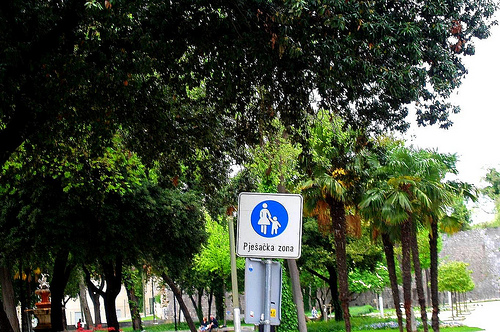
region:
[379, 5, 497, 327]
bright skies over trees and building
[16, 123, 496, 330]
grove of different types of green trees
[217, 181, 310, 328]
poles on either side of signs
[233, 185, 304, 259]
square sign with mother holding hands with child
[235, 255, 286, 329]
stickers placed on the back of a sign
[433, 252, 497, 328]
row of bright green trees at end of open lot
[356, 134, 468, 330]
narrow and long leaves on rough trunks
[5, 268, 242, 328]
tiered water fountain and buildings through trees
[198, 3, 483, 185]
dark green leaves over green and yellowish green leaves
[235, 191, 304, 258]
black print on sign in non-English language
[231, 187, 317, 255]
a white and blue sign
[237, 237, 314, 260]
black letters on a sign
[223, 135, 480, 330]
a few tall palm trees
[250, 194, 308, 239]
a blue circle on sign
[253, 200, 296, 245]
a woman and child on a sign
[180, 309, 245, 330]
two people sitting on a bench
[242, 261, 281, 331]
stickers on the back of a sign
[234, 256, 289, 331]
the gray back of a sign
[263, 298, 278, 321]
a yellow and black sticker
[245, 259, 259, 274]
a blue and white sticker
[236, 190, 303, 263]
The sign is white and blue.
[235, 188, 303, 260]
The sign is square.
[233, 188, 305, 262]
The sign depicts an adult and child.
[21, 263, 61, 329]
The fountain is made of stone.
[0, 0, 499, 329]
The trees are tall.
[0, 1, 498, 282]
The leaves are green.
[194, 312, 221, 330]
The people are relaxing.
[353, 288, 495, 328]
The water is clear.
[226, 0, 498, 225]
The sky is overcast.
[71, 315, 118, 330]
The flowers are red.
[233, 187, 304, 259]
road sign with a lady and child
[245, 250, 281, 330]
box under the road sign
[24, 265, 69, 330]
water fountain in the park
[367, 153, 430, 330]
tall palm tree in the distance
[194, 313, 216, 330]
people sittin on a park bench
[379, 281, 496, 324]
road adjacent to the park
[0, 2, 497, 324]
large tree overlooking the road sign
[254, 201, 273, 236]
stick figure representing the lady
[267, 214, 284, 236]
stick figure representing the child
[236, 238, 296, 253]
Words written in the polish language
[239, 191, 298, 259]
white and blue signboard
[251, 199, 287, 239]
circle blue symbol on white signboard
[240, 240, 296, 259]
finnish letters on white signboard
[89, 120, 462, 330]
small palms in the back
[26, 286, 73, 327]
red and beige water fountain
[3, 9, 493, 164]
big green branches of big tree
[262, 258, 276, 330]
gray pole where signboard is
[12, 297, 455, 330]
green grass in a park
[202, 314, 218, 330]
two people seated in a bench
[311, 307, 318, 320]
woman wearing light blue t-shirt seated in a bench